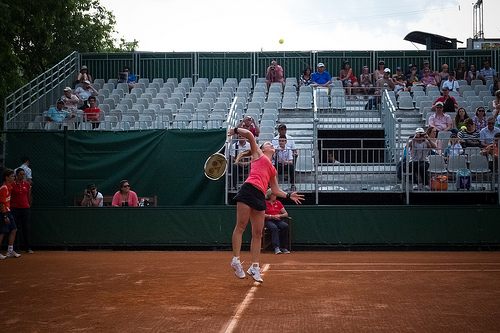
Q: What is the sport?
A: Tennis.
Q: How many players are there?
A: One.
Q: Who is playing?
A: A woman.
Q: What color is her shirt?
A: Pink.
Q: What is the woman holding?
A: A tennis racquet.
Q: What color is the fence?
A: Green.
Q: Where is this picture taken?
A: Tennis court.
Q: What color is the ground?
A: Brown.